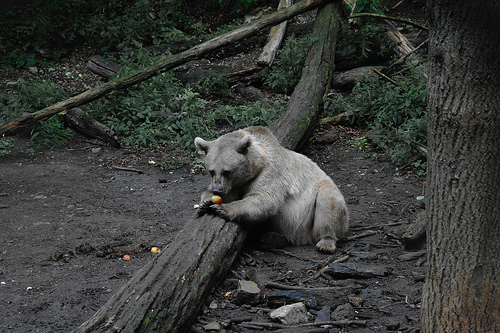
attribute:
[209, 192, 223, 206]
fruit — orange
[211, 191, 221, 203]
apple — red, green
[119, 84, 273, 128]
plants — green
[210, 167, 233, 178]
eyes — black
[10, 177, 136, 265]
floor — dirty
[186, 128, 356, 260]
bear — large, tan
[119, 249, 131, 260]
apple — longred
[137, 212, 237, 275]
trunk — long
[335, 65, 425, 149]
leaves — green